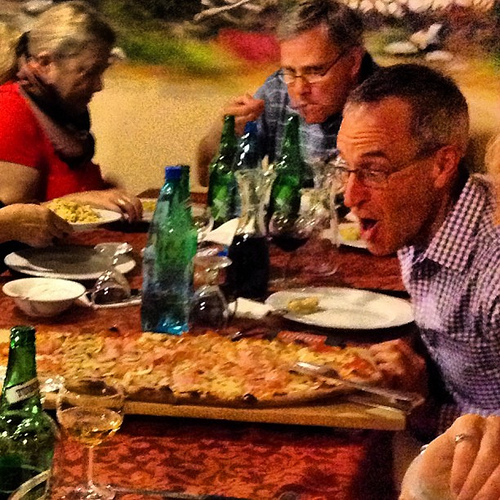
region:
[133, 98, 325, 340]
Lots of bottles on the table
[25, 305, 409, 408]
Some type of pizza on the table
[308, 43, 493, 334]
Look of amazement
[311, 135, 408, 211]
Glasses are square in shape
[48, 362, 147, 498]
Wine glass is full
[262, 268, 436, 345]
Plate is almost empty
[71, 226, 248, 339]
Upside down wine glasses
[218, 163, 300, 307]
Carafe of red wine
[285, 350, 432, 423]
Utensil for picking up the pizza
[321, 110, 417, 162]
Wrinkles on his forehead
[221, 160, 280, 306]
The carafe is over halfway filled.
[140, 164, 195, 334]
The bottle is blue.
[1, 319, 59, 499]
The bottle is green.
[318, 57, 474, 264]
The man is wearing glasses.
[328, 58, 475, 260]
The man's mouth is opened.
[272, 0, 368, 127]
The man is wearing glasses.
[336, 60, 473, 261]
The man has hair.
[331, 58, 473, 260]
The man's hair is short.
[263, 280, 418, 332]
The plate is white.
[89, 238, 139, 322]
The glass is upside down.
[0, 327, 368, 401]
a whole pizza pie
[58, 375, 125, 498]
a clear stemmed glass of wine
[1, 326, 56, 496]
a green glass beverage bottle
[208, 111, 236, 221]
a green glass beverage bottle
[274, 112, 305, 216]
a green glass beverage bottle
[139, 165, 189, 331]
a blue plastic beverage bottle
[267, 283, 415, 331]
a white food plate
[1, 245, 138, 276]
a white food plate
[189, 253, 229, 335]
a clear stemmed glass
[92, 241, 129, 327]
a clear stemmed glass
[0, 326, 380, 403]
A large pizza with many ingredients.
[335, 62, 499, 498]
A white man is about to have a feast.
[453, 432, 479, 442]
The white guy is wearing a ring.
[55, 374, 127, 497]
A regular glass of wine.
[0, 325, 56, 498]
A bottle of an alcoholic beverage.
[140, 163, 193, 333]
A plastic bottle of water.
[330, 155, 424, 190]
A pair of glasses in the man's face.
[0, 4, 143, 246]
An old white lady is sitting at the table.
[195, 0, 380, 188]
The man is eating some pasta.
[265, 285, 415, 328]
An empty plate with a spoon in it.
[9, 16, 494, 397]
people sitting at table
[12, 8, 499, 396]
people sitting at a table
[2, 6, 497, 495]
a person sitting at the table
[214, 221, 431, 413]
a white plate on table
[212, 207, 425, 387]
a plate on the table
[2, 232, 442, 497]
a pizza on the table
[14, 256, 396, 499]
a large pizza on a table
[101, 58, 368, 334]
glass bottles on the table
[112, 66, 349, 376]
green glass bottle on table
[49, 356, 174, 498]
wine glass on table